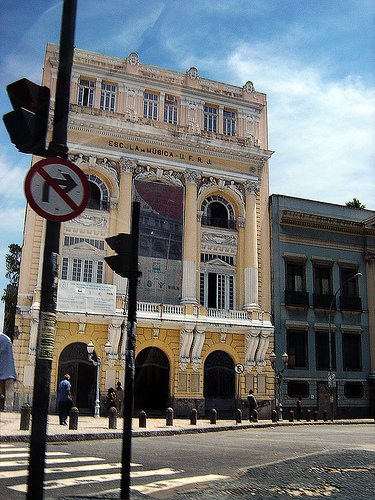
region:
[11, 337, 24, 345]
a brick on a wall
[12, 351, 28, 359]
a brick on a wall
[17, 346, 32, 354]
a brick on a wall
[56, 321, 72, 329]
a brick on a wall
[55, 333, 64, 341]
a brick on a wall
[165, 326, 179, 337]
a brick on a wall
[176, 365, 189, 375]
a brick on a wall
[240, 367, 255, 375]
a brick on a wall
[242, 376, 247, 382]
a brick on a wall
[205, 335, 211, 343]
a brick on a wall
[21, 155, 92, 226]
No right turn street sign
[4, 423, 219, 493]
White lines for a cross walk on the street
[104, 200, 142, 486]
Sign pole to indicate pedestrian crossing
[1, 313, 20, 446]
Left shoulder of a person crossing the street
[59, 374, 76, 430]
Man with a blue shirt walking on the sidewalk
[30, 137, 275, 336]
Large cream colored building with columns and large windows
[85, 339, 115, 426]
White street light with two lamps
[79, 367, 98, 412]
Person standing in an open doorway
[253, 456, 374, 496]
Side walk in need of repair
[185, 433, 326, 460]
Paved street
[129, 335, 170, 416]
An arched doorway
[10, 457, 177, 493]
White lines painted on a road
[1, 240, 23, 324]
A tree peeking around the side of a building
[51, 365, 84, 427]
A man walking alongside a road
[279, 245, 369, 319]
Three windows in a row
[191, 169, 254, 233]
An arched window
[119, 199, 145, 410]
A sign post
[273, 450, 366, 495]
Rough torn up street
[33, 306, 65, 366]
A poster glued to a light post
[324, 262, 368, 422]
A street light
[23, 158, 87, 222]
a no right turn sign on the pole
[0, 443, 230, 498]
a cross walk on the steet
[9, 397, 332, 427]
the road blocks on the sidewalk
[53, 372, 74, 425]
a man walking down the street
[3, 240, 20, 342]
a green tree next to the building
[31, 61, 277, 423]
a light colored building next to the sidewalk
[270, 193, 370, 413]
a darker colored building next to the other one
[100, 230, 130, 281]
some traffic lights on the pole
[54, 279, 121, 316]
a sign attached to the pole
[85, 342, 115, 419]
a street light on the sidewalk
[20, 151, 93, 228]
Arrow on a sign.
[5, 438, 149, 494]
White lines on the road.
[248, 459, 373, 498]
Holes in the road.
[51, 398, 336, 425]
Poles on the sidewalk.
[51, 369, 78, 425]
Man in blue shirt walking.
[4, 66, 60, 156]
Traffic light on a pole.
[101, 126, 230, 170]
Name on the building.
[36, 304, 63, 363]
Sticker on the sign.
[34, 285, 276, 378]
The building is yellow.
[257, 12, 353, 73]
The sky is blue.